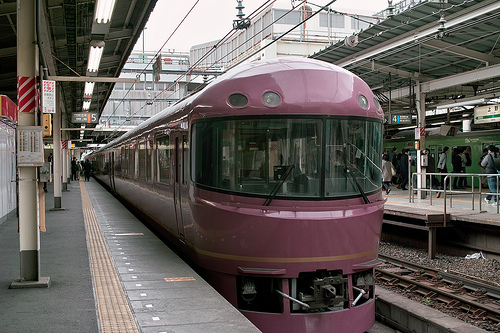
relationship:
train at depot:
[119, 97, 413, 298] [29, 32, 143, 273]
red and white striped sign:
[10, 72, 50, 127] [11, 71, 68, 122]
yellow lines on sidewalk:
[58, 183, 146, 331] [62, 166, 195, 329]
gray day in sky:
[172, 14, 213, 66] [161, 7, 194, 54]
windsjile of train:
[422, 143, 495, 206] [408, 113, 485, 193]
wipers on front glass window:
[264, 161, 387, 214] [231, 140, 385, 215]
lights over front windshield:
[201, 73, 402, 136] [199, 115, 391, 216]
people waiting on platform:
[60, 148, 119, 188] [70, 146, 136, 284]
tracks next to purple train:
[387, 225, 498, 323] [119, 97, 413, 298]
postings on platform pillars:
[23, 49, 59, 186] [14, 21, 83, 253]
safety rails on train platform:
[406, 166, 496, 216] [402, 169, 500, 240]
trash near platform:
[434, 233, 497, 284] [402, 169, 500, 240]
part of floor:
[57, 208, 104, 282] [52, 210, 80, 325]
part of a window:
[182, 130, 371, 195] [194, 130, 331, 216]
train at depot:
[408, 113, 485, 193] [29, 32, 143, 273]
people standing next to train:
[54, 118, 114, 225] [119, 97, 413, 298]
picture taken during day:
[7, 13, 484, 323] [165, 17, 223, 72]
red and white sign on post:
[10, 72, 50, 127] [9, 33, 94, 326]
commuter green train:
[119, 97, 413, 298] [408, 113, 485, 193]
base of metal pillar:
[16, 238, 56, 301] [16, 63, 71, 324]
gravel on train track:
[413, 241, 487, 285] [387, 225, 498, 323]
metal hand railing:
[407, 130, 499, 237] [402, 169, 500, 240]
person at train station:
[474, 138, 499, 198] [11, 11, 188, 333]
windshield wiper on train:
[242, 142, 334, 236] [408, 113, 485, 193]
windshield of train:
[242, 142, 334, 236] [408, 113, 485, 193]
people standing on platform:
[54, 118, 114, 225] [70, 146, 136, 284]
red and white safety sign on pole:
[10, 72, 50, 127] [7, 49, 59, 295]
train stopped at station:
[119, 97, 413, 298] [11, 11, 188, 333]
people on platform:
[69, 139, 103, 189] [0, 156, 250, 326]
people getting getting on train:
[408, 113, 485, 193] [85, 56, 385, 329]